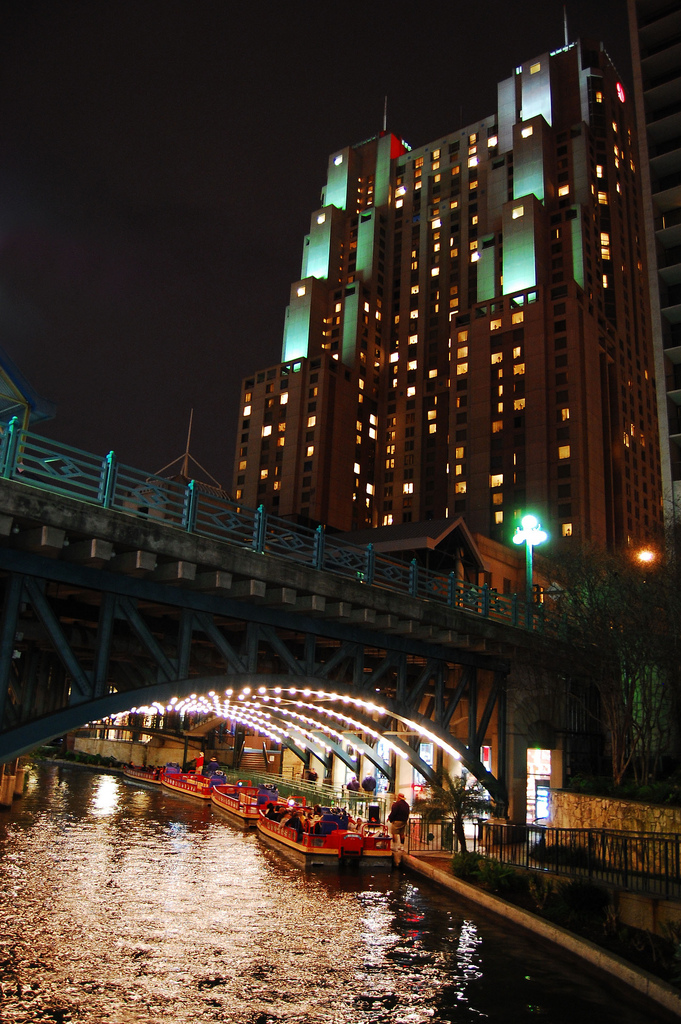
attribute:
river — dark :
[9, 741, 600, 1022]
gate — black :
[403, 812, 679, 900]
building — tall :
[225, 6, 663, 569]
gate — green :
[1, 414, 572, 634]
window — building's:
[266, 150, 573, 541]